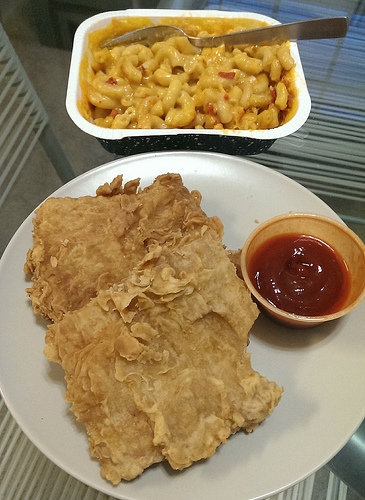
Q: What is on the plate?
A: Ketchup.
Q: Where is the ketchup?
A: Next to the food.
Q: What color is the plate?
A: White.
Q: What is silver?
A: A fork.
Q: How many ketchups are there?
A: One.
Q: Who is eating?
A: No one.